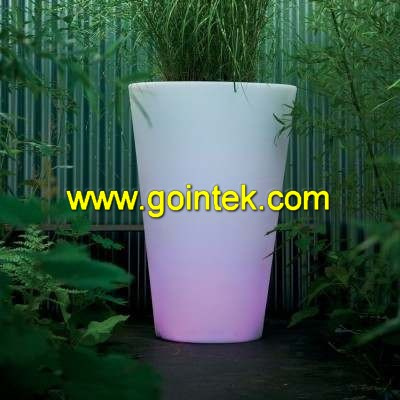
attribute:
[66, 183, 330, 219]
website — yellow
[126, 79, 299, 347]
planter — purple, white, lit, multicolored, round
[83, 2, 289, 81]
foliage — green, living, leafy, flourishing, verduous, growing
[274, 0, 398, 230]
tree — green, leafy, long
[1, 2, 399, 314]
wall — metal, tall, green